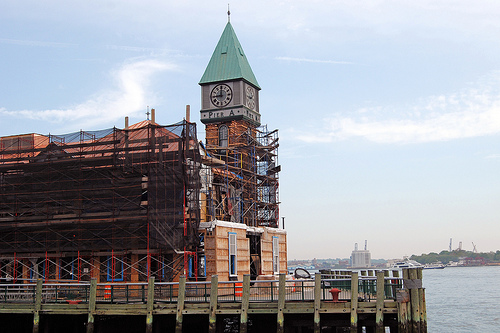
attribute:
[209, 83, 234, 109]
clock — white, gray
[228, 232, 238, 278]
window — large, white, rectangular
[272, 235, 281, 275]
window — large, white, rectangular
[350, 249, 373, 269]
building — white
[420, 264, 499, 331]
water — blue, clear, flowing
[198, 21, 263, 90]
roof — green, pointed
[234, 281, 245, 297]
barrel — orange, striped, white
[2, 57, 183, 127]
cloud — white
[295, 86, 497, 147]
cloud — white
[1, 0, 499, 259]
sky — blue, clear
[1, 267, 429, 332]
dock — wooden, wood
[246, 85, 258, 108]
clock — white, gray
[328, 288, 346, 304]
hydrant — red, metal